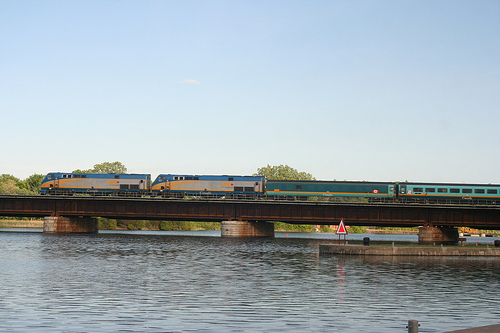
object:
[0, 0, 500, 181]
sky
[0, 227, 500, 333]
water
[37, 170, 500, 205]
train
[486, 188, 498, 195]
windows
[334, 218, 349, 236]
sign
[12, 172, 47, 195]
tree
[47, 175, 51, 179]
pilot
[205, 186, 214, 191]
engines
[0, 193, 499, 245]
bridge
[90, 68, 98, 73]
clouds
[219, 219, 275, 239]
stumps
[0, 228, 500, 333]
lake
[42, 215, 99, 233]
pillars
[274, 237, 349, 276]
shadow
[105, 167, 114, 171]
trees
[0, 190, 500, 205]
railing